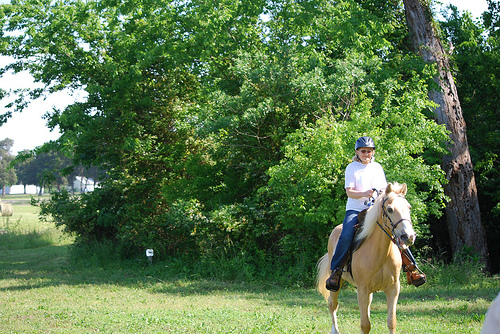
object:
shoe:
[324, 266, 345, 291]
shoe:
[401, 260, 426, 287]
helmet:
[354, 135, 376, 152]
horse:
[314, 181, 417, 334]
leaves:
[155, 162, 224, 218]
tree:
[20, 0, 439, 259]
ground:
[0, 278, 499, 333]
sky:
[10, 112, 45, 146]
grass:
[0, 276, 491, 332]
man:
[326, 134, 426, 293]